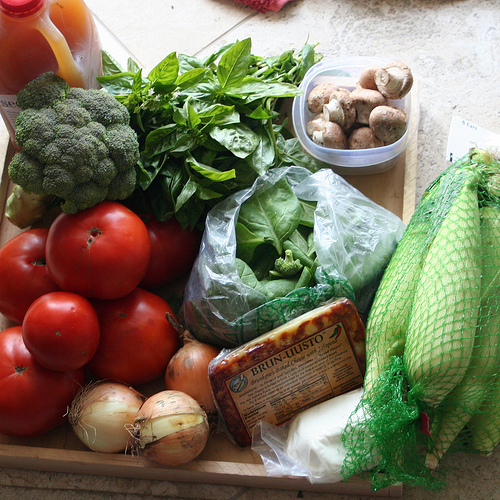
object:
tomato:
[47, 201, 150, 300]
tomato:
[20, 291, 100, 373]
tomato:
[0, 229, 76, 324]